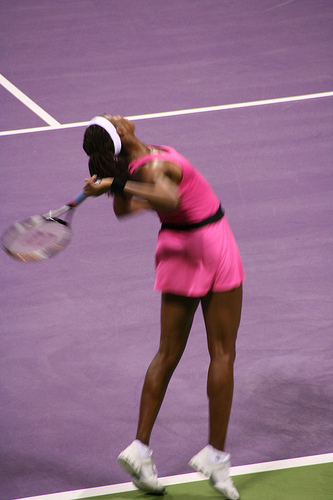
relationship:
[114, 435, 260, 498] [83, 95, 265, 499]
feet of a person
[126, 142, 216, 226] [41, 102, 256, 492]
tank on woman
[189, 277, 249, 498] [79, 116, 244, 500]
leg of player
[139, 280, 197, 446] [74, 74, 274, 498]
leg of woman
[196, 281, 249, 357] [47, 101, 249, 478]
thigh of person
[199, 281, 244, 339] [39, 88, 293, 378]
thigh of person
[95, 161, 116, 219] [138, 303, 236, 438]
headband on ten player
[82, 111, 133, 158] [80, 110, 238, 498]
head of a person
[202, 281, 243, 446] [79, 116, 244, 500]
leg of a player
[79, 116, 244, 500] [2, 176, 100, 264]
player holding racquet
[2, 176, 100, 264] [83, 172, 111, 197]
racquet in hand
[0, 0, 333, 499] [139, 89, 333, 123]
tennis court with white line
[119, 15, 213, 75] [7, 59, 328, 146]
tennis court with white lines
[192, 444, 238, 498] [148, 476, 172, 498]
feet on top toes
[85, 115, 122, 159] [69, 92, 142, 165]
headband on head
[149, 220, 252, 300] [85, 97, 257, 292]
skirt on player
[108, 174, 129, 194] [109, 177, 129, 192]
wristband on wrist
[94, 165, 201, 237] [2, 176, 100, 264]
hand holding racquet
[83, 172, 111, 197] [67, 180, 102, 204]
hand on grip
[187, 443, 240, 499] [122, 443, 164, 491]
shoe on foot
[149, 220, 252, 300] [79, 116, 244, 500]
skirt on player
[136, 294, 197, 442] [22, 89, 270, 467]
leg of person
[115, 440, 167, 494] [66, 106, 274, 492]
foot of person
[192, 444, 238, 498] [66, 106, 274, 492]
feet of person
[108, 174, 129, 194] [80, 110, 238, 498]
wristband of person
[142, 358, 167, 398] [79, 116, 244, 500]
calf muscle of player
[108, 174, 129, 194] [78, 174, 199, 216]
wristband on arm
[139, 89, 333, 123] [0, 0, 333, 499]
white line on tennis court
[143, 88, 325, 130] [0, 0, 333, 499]
white line on tennis court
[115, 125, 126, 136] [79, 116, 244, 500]
ear of player